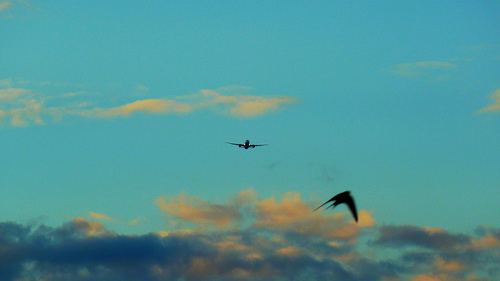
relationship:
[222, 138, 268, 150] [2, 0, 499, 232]
airplane in sky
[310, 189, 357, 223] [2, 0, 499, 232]
bird in sky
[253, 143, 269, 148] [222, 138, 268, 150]
wing on airplane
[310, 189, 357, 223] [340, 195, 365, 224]
bird has wing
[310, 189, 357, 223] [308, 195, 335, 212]
bird has wing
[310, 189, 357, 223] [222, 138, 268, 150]
bird flying near airplane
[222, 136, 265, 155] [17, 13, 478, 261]
airplane flying in sky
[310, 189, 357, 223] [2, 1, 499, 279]
bird in sky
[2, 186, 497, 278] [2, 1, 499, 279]
cloud in sky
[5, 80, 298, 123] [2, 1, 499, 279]
cloud in sky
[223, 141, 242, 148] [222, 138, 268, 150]
wing on side of airplane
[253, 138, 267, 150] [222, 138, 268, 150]
wing on airplane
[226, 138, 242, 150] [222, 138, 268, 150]
wing on airplane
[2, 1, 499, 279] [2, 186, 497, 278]
sky with cloud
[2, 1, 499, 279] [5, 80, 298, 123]
sky with cloud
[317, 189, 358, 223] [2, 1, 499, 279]
bird flying through sky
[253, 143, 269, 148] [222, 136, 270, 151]
wing of airplane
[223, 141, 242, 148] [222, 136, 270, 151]
wing of airplane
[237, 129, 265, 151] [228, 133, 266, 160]
nose of airplane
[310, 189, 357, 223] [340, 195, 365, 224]
bird flapping h wing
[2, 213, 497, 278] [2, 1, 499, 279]
cloud in sky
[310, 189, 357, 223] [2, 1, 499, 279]
bird flying through sky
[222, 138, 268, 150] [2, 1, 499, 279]
airplane flying through sky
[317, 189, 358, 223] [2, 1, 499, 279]
bird flying in sky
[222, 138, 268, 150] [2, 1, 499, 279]
airplane flying in sky